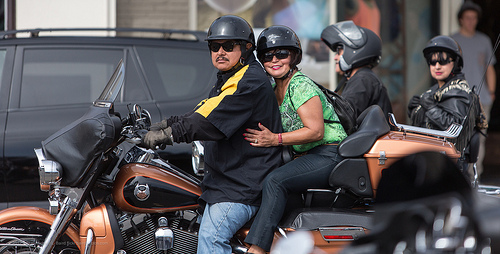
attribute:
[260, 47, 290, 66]
sunglasses — BLACK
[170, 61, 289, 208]
shirt — BLACK, YELLOW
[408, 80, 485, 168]
jacket — LEATHER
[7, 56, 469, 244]
motorcycle — GOLD, BLACK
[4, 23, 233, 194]
car — BLACK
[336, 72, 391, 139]
jacket — BLACK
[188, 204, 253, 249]
pants — JEANS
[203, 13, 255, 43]
helmet — BLACK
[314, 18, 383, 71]
helmet — black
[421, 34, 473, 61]
helmet — black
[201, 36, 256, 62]
sunglasses — black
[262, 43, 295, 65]
sunglasses — black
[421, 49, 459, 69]
sunglasses — black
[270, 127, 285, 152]
bracelet — pink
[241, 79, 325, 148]
arm — woman's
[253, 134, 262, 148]
ring — wedding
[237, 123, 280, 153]
hand — woman's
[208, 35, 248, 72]
face — man's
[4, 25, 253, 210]
suv — black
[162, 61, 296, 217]
shirt — black, yellow, man's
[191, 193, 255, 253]
jeans — man's, blue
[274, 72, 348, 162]
blouse — woman's, green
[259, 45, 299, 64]
sunglasses — black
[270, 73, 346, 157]
shirt — green